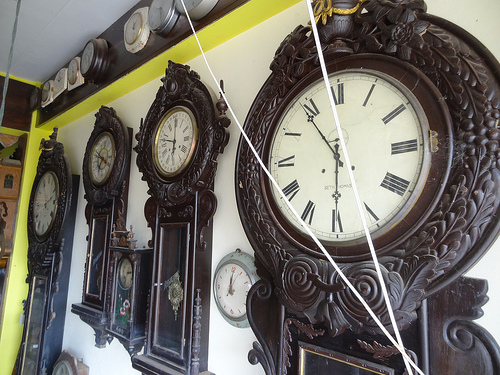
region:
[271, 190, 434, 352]
two pieces of white string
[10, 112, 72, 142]
yellow borders on edge of wall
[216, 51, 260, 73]
portion of solid white wall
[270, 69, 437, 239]
white round face of big clock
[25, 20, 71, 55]
portion of blue ceiling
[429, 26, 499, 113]
decorative section of dark brown clock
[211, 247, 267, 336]
small light gray clock on wall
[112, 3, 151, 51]
small white clock on wall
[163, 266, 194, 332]
white decorative symbol on clock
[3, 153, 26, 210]
portion of wooden box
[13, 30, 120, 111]
Four round clocks on a wall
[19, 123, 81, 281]
a white clock face on a brown wall clock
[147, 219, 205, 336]
a gold pendulum in a brown wall clock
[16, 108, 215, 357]
Four brown wall clocks on a white wall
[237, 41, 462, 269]
a white clock face on a brown wooden wall clock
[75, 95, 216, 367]
a smaller wall clock between two larger clocks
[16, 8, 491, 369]
a white wall with many clocks on it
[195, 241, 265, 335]
a clock pointing to 12:00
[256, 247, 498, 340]
decoratively carved wood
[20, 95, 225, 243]
three clock faces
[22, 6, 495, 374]
NUMEROUS CLOCKS ON THE WALL.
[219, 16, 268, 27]
YELLOW PAINT ON WHITE WALL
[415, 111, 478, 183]
SPIDER WEBS AND DUST ON CLOCK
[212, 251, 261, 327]
SMALL SILVER CLOCK READING TWELVE O'CLOCK.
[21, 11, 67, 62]
DROP CEILING WITH WHITE CEILING TOWELS.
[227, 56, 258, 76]
WHITE PAINT COVERING WALL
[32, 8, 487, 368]
WALL OF CLOCKS WITH DIFFERENT TIMES.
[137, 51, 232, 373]
DIRTY OLD CLOCK WITH THE WRONG TIME.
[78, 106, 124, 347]
DIRTY OLD CLOCK WITH THE WRONG TIME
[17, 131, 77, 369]
DIRTY OLD CLOCK WITH THE WRONG TIME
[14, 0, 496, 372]
several clocks on a wall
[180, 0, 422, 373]
two white cords in front of a clock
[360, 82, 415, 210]
roman numerals on a clock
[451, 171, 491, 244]
dark carving on a clock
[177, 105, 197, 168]
a metallic ring around a clock face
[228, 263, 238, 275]
the number 12 on a clock face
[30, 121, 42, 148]
yellow paint on a wall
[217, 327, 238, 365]
the wall is painted white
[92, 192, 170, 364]
a smaller clock between two larger clocks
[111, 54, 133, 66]
black paint on a wall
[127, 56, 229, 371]
ornate wall clock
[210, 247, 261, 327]
round clock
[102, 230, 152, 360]
small hanging clock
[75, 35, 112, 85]
round brown clock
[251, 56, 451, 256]
round clock face with roman numerals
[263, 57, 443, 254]
the time is 5:54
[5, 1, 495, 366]
clocks hanging on the wall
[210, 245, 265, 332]
a round grey clock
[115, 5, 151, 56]
white clock hanging on the wall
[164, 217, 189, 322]
pendulum hanging inside a hanging clock